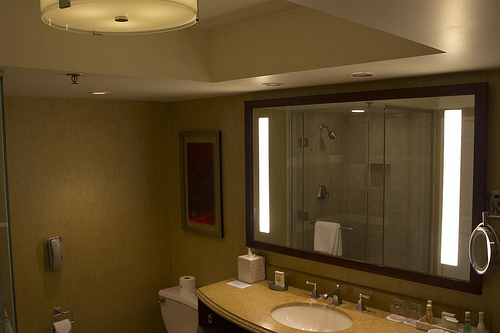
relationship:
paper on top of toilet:
[179, 276, 195, 294] [155, 281, 201, 333]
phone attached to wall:
[44, 236, 65, 272] [9, 97, 197, 332]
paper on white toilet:
[179, 276, 195, 294] [158, 286, 198, 332]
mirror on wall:
[247, 96, 489, 285] [8, 89, 438, 332]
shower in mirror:
[320, 123, 337, 139] [225, 87, 487, 301]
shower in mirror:
[288, 111, 436, 248] [247, 96, 489, 285]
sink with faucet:
[262, 295, 369, 331] [302, 272, 373, 315]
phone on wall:
[44, 236, 65, 272] [22, 90, 176, 329]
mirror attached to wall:
[468, 230, 498, 278] [158, 75, 498, 326]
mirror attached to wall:
[252, 94, 476, 284] [158, 75, 498, 326]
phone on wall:
[47, 236, 65, 275] [72, 142, 145, 276]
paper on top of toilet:
[178, 273, 194, 295] [158, 275, 205, 327]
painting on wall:
[172, 123, 229, 240] [152, 111, 248, 287]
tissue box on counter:
[237, 244, 262, 282] [199, 277, 495, 330]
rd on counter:
[209, 273, 264, 295] [197, 270, 454, 331]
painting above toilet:
[172, 123, 229, 240] [157, 280, 204, 331]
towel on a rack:
[318, 211, 346, 266] [306, 206, 371, 242]